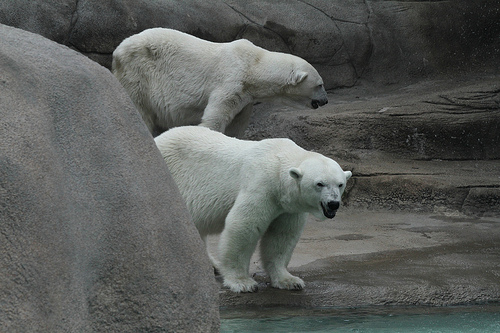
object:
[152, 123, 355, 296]
bear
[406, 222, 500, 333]
right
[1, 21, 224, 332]
boulder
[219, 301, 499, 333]
water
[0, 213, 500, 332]
foreground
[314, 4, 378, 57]
crack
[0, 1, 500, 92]
boulder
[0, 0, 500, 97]
background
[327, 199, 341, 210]
nose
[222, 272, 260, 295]
paws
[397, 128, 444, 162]
spots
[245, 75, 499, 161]
rock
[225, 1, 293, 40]
cracks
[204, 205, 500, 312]
rocks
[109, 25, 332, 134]
bears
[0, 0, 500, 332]
area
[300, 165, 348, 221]
face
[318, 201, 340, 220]
mouth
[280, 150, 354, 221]
head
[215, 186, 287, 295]
legs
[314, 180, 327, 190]
eyes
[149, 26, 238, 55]
back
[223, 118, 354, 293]
positions